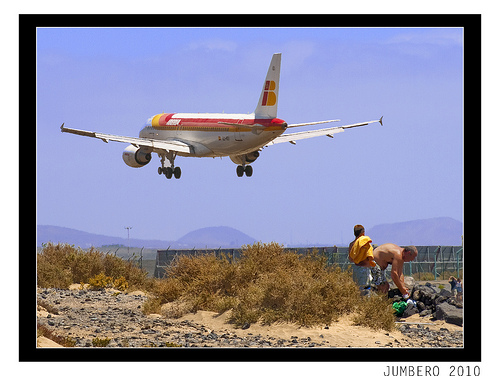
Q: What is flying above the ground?
A: An airplane.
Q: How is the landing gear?
A: Landing gear is down.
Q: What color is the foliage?
A: Brown.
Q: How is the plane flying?
A: Flying low.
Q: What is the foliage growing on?
A: Sand.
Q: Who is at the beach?
A: Two men.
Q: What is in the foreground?
A: Bushes and sand.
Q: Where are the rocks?
A: On the ground.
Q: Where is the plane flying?
A: At low altitude.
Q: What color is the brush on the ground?
A: Brown.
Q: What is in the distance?
A: A tall fence.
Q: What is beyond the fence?
A: Blue hills.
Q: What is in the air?
A: A large airplane.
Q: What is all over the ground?
A: Rocks.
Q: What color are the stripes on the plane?
A: Yellow and red.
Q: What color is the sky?
A: Blue.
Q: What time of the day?
A: Daytime.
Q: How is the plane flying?
A: A bit low from the ground.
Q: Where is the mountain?
A: In the background.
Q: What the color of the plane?
A: White and red.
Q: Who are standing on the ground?
A: Two men.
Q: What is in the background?
A: Mountains.